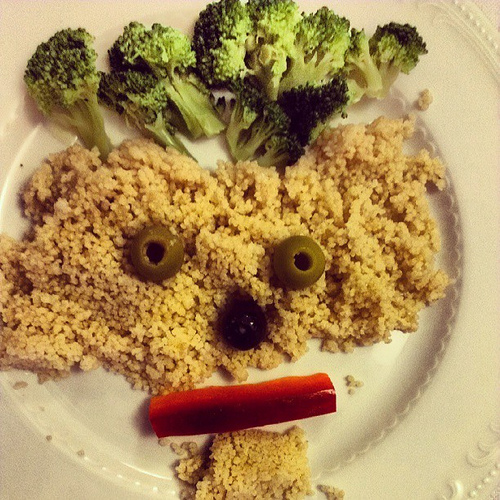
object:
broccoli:
[22, 28, 114, 161]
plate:
[0, 0, 499, 498]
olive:
[125, 219, 188, 284]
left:
[87, 169, 205, 267]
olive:
[272, 232, 326, 290]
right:
[282, 199, 398, 328]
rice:
[80, 222, 106, 250]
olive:
[219, 294, 270, 350]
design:
[355, 415, 428, 459]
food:
[144, 173, 284, 365]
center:
[0, 67, 462, 495]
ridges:
[437, 167, 470, 339]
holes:
[144, 237, 168, 268]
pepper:
[150, 371, 338, 439]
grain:
[185, 427, 312, 499]